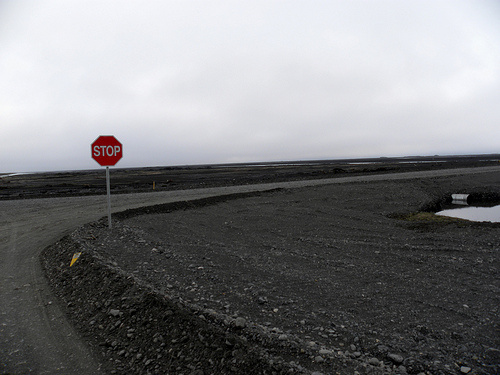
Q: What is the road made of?
A: Gravel, sand, and stones.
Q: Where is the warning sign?
A: By the road.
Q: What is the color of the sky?
A: Gray and white.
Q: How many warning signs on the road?
A: One.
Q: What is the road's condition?
A: Incomplete.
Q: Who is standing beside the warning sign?
A: No one.